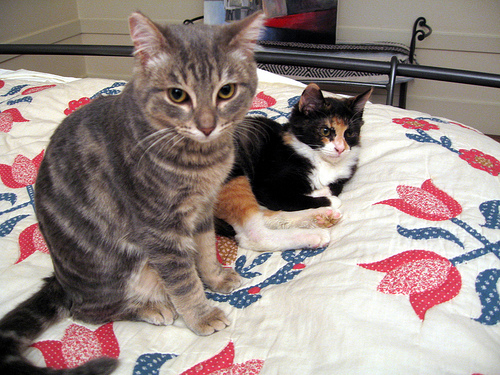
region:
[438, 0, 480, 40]
part of a wall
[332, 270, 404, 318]
part of a duvet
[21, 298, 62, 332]
part of a tail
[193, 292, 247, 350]
part of a paw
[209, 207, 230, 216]
chest of a cat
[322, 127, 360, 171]
part of a cat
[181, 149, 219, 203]
chest of a cat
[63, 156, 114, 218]
stomach of a cat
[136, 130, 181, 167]
whiskers of a cat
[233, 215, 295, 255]
part of a leg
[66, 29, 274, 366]
grey and white cat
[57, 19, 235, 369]
cat sitting on bed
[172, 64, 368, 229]
black and white and brown cat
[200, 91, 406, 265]
cat laying on bed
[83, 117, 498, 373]
white blanket on bed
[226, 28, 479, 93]
black metal pole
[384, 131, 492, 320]
red flowers on bed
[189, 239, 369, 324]
blue flower stems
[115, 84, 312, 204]
white whiskers of cat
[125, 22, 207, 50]
white hair in cats ear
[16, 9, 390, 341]
two cats next to each other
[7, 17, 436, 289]
two cats on a bed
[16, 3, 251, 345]
a cat sitting on a bed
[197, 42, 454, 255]
a cat laying down on the bed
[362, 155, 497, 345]
a red flower quilt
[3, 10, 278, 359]
a grey striped cat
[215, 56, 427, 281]
black orange white cat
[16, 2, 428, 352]
two cats laying on a quilt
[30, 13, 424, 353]
two cats inside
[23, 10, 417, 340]
two cats being still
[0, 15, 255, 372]
Light black and light brown cat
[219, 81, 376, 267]
Dark black, white, and orange cat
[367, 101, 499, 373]
Portion of a bedspread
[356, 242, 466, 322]
Red tulip on bedspread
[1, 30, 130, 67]
Black, metal bar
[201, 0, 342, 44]
Painting or poster against the wall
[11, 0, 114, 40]
White wall in the background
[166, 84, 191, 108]
Yellow and black cat eye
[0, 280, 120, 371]
Cat's tail on the bedspread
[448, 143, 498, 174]
Red type of flower on bedspread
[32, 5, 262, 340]
Black, brown and white cat sitting on the bed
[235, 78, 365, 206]
Black and white cat laying on the bed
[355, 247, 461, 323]
Light and dark pink tulip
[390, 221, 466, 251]
Blue and white leaf of tulip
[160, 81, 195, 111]
Right eye of black, brown and white cat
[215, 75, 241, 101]
Black, brown and white cat's left eye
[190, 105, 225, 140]
Nose of black, brown and white cat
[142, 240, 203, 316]
Right leg of black, brown and white cat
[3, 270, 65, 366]
Tail of black, brown and white cat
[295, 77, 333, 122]
Right ear of black and white cat